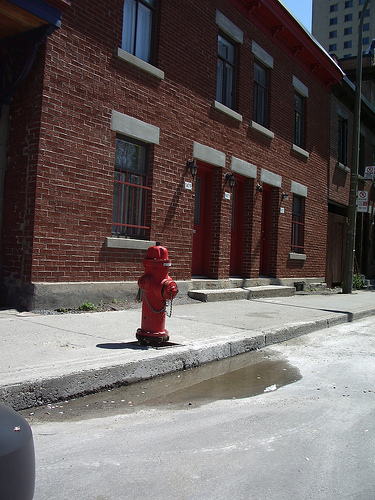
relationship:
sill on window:
[116, 44, 168, 83] [120, 0, 158, 66]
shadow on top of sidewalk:
[257, 295, 353, 320] [0, 295, 374, 411]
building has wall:
[0, 3, 373, 309] [30, 0, 110, 283]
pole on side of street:
[339, 0, 373, 297] [20, 315, 374, 498]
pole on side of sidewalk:
[339, 0, 373, 297] [0, 295, 374, 411]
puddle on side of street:
[21, 347, 301, 424] [20, 315, 374, 498]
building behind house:
[315, 1, 374, 81] [0, 3, 373, 309]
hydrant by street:
[135, 241, 178, 348] [20, 315, 374, 498]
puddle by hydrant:
[21, 347, 301, 424] [135, 241, 178, 348]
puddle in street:
[21, 347, 301, 424] [20, 315, 374, 498]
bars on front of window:
[112, 171, 150, 232] [109, 136, 158, 239]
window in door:
[194, 182, 202, 222] [192, 170, 212, 275]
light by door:
[191, 158, 200, 173] [192, 170, 212, 275]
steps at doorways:
[188, 287, 297, 303] [192, 152, 282, 281]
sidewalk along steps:
[0, 295, 374, 411] [188, 287, 297, 303]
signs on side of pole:
[356, 186, 368, 209] [339, 0, 373, 297]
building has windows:
[315, 1, 374, 81] [328, 6, 366, 48]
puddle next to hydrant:
[21, 347, 301, 424] [135, 241, 178, 348]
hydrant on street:
[135, 241, 178, 348] [20, 315, 374, 498]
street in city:
[20, 315, 374, 498] [2, 3, 371, 496]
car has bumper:
[3, 403, 37, 499] [3, 403, 35, 499]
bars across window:
[112, 171, 150, 232] [109, 136, 158, 239]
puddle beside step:
[21, 347, 301, 424] [0, 307, 371, 409]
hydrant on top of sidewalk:
[135, 241, 178, 348] [0, 295, 374, 411]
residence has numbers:
[0, 3, 373, 309] [185, 181, 288, 217]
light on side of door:
[191, 158, 200, 173] [192, 170, 212, 275]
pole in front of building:
[339, 0, 373, 297] [0, 3, 373, 309]